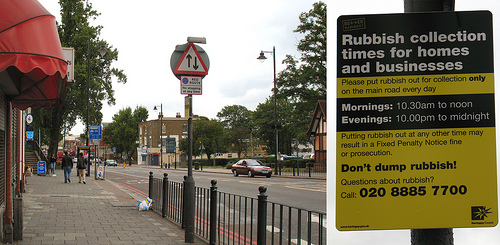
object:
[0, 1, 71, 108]
awning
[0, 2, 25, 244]
building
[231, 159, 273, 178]
car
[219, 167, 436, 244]
street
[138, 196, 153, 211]
bag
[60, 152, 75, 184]
people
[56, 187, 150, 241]
people sidewalk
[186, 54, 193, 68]
arrow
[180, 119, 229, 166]
tree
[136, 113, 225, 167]
brown building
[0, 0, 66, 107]
awing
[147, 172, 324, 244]
fence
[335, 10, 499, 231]
sign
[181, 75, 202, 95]
sign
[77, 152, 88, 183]
people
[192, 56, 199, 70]
arrow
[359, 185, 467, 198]
number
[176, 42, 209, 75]
sign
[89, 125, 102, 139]
blue sign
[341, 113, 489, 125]
times